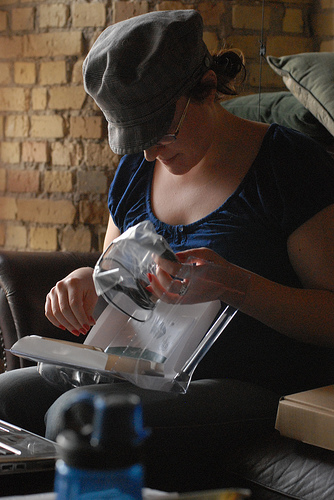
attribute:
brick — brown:
[12, 205, 70, 262]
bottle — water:
[54, 389, 150, 497]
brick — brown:
[25, 215, 61, 254]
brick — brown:
[15, 192, 104, 226]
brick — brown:
[0, 194, 17, 221]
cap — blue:
[81, 9, 205, 150]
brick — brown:
[3, 159, 40, 196]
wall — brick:
[27, 19, 77, 79]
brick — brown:
[77, 198, 108, 222]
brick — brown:
[58, 223, 92, 251]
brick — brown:
[264, 33, 315, 56]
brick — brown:
[34, 58, 67, 83]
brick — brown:
[19, 31, 84, 56]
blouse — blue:
[104, 119, 326, 357]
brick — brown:
[70, 163, 113, 197]